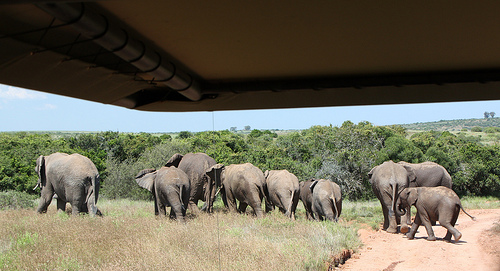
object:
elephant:
[364, 158, 452, 235]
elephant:
[296, 177, 343, 223]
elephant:
[260, 167, 299, 223]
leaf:
[211, 149, 224, 159]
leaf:
[3, 162, 15, 169]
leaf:
[28, 141, 42, 149]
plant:
[0, 120, 499, 202]